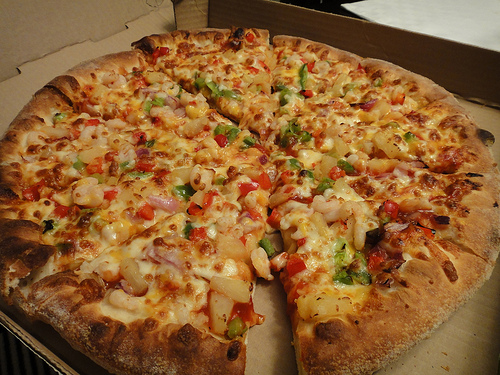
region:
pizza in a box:
[3, 22, 489, 362]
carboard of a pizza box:
[462, 310, 496, 360]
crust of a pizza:
[387, 291, 440, 344]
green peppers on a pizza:
[330, 262, 375, 293]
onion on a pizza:
[147, 193, 178, 212]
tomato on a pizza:
[134, 196, 257, 223]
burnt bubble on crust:
[313, 316, 355, 341]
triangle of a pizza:
[298, 144, 498, 261]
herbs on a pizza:
[301, 294, 352, 317]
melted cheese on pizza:
[151, 268, 195, 329]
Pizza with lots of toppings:
[1, 28, 497, 373]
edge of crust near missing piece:
[274, 306, 344, 372]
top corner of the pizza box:
[154, 0, 268, 47]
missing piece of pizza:
[232, 194, 309, 373]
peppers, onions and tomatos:
[143, 169, 215, 226]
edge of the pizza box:
[4, 305, 58, 370]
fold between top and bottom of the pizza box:
[27, 21, 137, 46]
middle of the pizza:
[204, 133, 286, 210]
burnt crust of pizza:
[3, 235, 58, 292]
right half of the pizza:
[239, 30, 496, 372]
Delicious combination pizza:
[0, 25, 497, 373]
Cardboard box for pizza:
[1, 2, 496, 370]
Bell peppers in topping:
[45, 54, 457, 351]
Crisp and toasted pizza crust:
[0, 25, 495, 366]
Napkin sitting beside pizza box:
[337, 0, 497, 55]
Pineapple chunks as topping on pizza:
[37, 45, 429, 330]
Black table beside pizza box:
[265, 0, 495, 25]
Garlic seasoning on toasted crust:
[0, 25, 491, 370]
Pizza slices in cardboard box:
[0, 25, 495, 370]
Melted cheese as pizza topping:
[18, 45, 473, 345]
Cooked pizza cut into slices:
[0, 10, 478, 373]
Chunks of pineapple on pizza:
[203, 270, 258, 310]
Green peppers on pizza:
[319, 233, 379, 302]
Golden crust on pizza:
[243, 240, 480, 372]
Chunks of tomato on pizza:
[129, 197, 164, 225]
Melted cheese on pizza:
[36, 48, 499, 345]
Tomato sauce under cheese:
[45, 25, 444, 338]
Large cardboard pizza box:
[3, 9, 490, 355]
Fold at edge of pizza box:
[2, 6, 220, 136]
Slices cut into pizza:
[148, 59, 494, 303]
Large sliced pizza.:
[10, 24, 499, 371]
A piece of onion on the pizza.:
[209, 275, 250, 303]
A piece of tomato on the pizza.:
[136, 202, 154, 219]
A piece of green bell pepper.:
[209, 83, 231, 99]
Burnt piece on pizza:
[228, 341, 240, 360]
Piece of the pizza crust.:
[403, 274, 455, 311]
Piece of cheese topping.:
[158, 280, 203, 320]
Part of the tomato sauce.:
[233, 298, 263, 334]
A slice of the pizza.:
[142, 28, 275, 132]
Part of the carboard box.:
[23, 8, 123, 48]